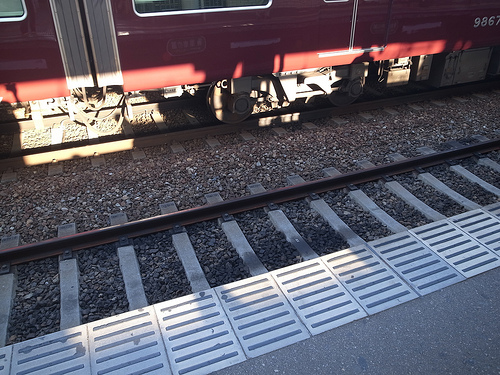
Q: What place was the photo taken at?
A: It was taken at the pavement.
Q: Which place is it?
A: It is a pavement.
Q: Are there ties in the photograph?
A: Yes, there is a tie.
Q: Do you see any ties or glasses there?
A: Yes, there is a tie.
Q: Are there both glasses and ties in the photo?
A: No, there is a tie but no glasses.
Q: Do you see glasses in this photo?
A: No, there are no glasses.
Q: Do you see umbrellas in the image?
A: No, there are no umbrellas.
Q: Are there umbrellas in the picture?
A: No, there are no umbrellas.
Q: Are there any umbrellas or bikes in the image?
A: No, there are no umbrellas or bikes.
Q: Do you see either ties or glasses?
A: Yes, there is a tie.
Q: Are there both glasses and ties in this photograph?
A: No, there is a tie but no glasses.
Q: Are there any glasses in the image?
A: No, there are no glasses.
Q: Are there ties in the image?
A: Yes, there is a tie.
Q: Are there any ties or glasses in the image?
A: Yes, there is a tie.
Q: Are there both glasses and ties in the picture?
A: No, there is a tie but no glasses.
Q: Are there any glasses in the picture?
A: No, there are no glasses.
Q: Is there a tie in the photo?
A: Yes, there is a tie.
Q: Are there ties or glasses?
A: Yes, there is a tie.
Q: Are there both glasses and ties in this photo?
A: No, there is a tie but no glasses.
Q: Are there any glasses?
A: No, there are no glasses.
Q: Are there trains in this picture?
A: Yes, there is a train.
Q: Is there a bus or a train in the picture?
A: Yes, there is a train.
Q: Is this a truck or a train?
A: This is a train.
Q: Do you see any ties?
A: Yes, there is a tie.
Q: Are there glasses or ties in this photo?
A: Yes, there is a tie.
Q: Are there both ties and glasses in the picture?
A: No, there is a tie but no glasses.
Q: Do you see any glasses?
A: No, there are no glasses.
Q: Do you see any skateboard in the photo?
A: No, there are no skateboards.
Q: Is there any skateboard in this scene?
A: No, there are no skateboards.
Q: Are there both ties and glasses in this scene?
A: No, there is a tie but no glasses.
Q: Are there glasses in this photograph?
A: No, there are no glasses.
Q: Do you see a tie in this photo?
A: Yes, there is a tie.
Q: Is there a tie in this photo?
A: Yes, there is a tie.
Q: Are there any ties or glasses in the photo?
A: Yes, there is a tie.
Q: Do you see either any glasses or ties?
A: Yes, there is a tie.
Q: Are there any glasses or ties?
A: Yes, there is a tie.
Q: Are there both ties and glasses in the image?
A: No, there is a tie but no glasses.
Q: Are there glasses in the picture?
A: No, there are no glasses.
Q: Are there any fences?
A: No, there are no fences.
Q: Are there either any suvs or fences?
A: No, there are no fences or suvs.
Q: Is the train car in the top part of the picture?
A: Yes, the train car is in the top of the image.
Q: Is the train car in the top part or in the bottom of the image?
A: The train car is in the top of the image.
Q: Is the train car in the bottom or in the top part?
A: The train car is in the top of the image.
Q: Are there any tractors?
A: No, there are no tractors.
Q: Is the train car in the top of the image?
A: Yes, the train car is in the top of the image.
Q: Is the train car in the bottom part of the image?
A: No, the train car is in the top of the image.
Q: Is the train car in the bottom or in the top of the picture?
A: The train car is in the top of the image.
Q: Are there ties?
A: Yes, there is a tie.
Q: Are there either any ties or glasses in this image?
A: Yes, there is a tie.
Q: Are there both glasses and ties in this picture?
A: No, there is a tie but no glasses.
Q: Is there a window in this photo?
A: Yes, there is a window.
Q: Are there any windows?
A: Yes, there is a window.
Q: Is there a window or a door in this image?
A: Yes, there is a window.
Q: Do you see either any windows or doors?
A: Yes, there is a window.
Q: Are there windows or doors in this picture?
A: Yes, there is a window.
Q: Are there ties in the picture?
A: Yes, there is a tie.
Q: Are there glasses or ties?
A: Yes, there is a tie.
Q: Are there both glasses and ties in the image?
A: No, there is a tie but no glasses.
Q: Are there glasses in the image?
A: No, there are no glasses.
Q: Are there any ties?
A: Yes, there is a tie.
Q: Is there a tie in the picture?
A: Yes, there is a tie.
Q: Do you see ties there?
A: Yes, there is a tie.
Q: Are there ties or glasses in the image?
A: Yes, there is a tie.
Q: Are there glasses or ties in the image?
A: Yes, there is a tie.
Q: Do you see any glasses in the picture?
A: No, there are no glasses.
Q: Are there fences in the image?
A: No, there are no fences.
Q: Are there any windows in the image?
A: Yes, there is a window.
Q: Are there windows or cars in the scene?
A: Yes, there is a window.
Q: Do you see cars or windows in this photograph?
A: Yes, there is a window.